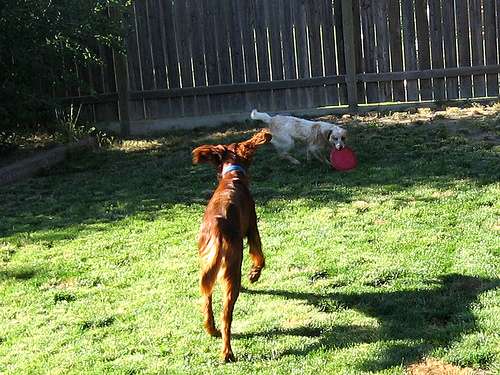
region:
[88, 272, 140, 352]
green grass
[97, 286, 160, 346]
green grass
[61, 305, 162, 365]
green grass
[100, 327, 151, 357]
green grass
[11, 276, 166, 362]
green grass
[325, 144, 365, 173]
a red frisbee in a dog's mouth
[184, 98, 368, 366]
two dogs playing with a frisbee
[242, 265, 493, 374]
the shadow of a dog on the grass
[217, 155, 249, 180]
a blue collar on a dog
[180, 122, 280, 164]
two dog ears flying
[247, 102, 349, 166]
a white dog in the shadows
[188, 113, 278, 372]
a red dog running at a white dog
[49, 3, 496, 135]
a wooden privacy fence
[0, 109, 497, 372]
a green grassy lawn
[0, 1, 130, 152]
a tree growing next to a fence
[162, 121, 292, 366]
brown dog in a yard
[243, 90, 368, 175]
dog holding a frisbee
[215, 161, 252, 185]
a blue dog collar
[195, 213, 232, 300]
tail of a dog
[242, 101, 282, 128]
tail of a dog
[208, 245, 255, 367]
hind leg of the dog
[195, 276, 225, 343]
hind leg on the dog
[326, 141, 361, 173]
red frisbee in a dogs mouth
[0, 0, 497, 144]
fence made of wooden boards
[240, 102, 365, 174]
dog with a frisbee in its mouth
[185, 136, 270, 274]
dog in the grass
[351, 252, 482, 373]
shadow on the ground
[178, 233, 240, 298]
tail of the dog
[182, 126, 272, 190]
head of the dog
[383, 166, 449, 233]
light and dark grass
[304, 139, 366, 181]
Frisbee in dog's mouth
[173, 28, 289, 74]
fence in the background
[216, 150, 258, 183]
collar on the dog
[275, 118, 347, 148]
white dog in the grass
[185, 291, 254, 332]
back legs of the dog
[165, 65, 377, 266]
two dogs are playing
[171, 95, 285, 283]
two dogs are playing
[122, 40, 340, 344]
two dogs are playing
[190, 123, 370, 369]
two dogs are playing